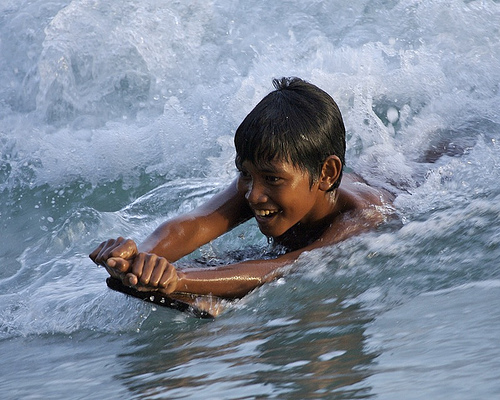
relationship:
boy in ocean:
[129, 89, 384, 302] [0, 0, 500, 400]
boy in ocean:
[129, 89, 384, 302] [357, 3, 474, 58]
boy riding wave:
[129, 89, 384, 302] [267, 337, 441, 362]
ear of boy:
[315, 146, 343, 188] [129, 89, 384, 302]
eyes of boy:
[227, 164, 289, 191] [129, 89, 384, 302]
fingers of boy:
[112, 258, 187, 290] [129, 89, 384, 302]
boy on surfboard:
[129, 89, 384, 302] [116, 292, 198, 316]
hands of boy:
[82, 239, 135, 261] [129, 89, 384, 302]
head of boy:
[242, 52, 337, 245] [129, 89, 384, 302]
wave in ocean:
[267, 337, 441, 362] [357, 3, 474, 58]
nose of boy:
[237, 186, 279, 206] [129, 89, 384, 302]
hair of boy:
[240, 94, 340, 157] [129, 89, 384, 302]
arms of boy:
[162, 218, 269, 278] [129, 89, 384, 302]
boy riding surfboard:
[129, 89, 384, 302] [116, 292, 198, 316]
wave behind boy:
[267, 337, 441, 362] [129, 89, 384, 302]